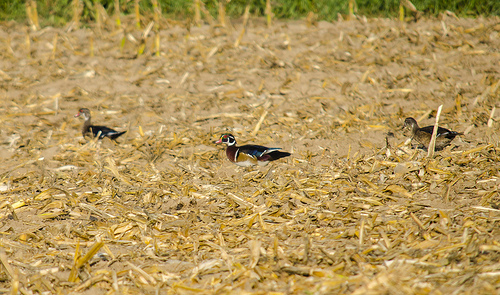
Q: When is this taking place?
A: Daytime.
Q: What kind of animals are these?
A: Ducks.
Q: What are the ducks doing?
A: Walking.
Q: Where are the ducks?
A: In the straw.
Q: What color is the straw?
A: Yellow.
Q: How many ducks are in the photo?
A: Three.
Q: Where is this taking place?
A: In a field.